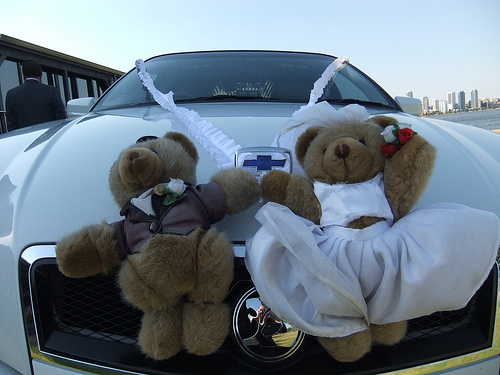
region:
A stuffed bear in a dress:
[254, 107, 499, 359]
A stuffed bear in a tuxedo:
[58, 129, 260, 359]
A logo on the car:
[234, 148, 291, 176]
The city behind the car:
[424, 90, 496, 114]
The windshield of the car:
[99, 54, 400, 108]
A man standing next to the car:
[3, 62, 67, 120]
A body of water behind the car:
[423, 107, 498, 130]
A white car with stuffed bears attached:
[2, 51, 497, 374]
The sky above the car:
[1, 0, 497, 102]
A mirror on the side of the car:
[397, 97, 421, 113]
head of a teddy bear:
[89, 112, 216, 207]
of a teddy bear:
[286, 99, 413, 198]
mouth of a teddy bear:
[119, 145, 162, 190]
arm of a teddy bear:
[55, 204, 115, 279]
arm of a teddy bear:
[220, 145, 274, 227]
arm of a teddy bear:
[254, 170, 313, 220]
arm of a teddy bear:
[393, 127, 445, 181]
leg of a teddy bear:
[128, 287, 210, 370]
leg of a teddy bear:
[171, 285, 245, 362]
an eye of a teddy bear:
[312, 127, 342, 163]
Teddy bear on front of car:
[53, 126, 255, 356]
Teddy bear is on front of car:
[52, 125, 252, 360]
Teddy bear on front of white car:
[45, 125, 255, 355]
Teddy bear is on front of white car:
[41, 122, 256, 362]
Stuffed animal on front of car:
[45, 124, 261, 362]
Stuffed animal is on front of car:
[47, 124, 262, 364]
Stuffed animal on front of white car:
[50, 125, 260, 363]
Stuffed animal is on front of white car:
[45, 127, 263, 362]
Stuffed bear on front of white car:
[53, 125, 260, 358]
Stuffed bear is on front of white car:
[52, 125, 261, 363]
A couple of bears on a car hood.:
[51, 107, 498, 366]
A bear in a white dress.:
[252, 83, 492, 348]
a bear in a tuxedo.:
[46, 125, 253, 366]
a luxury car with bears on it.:
[2, 46, 495, 372]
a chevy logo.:
[210, 135, 308, 191]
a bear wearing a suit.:
[108, 156, 240, 277]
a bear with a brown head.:
[90, 120, 195, 221]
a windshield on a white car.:
[73, 43, 398, 118]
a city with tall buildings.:
[400, 80, 480, 111]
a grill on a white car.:
[11, 231, 493, 365]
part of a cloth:
[417, 257, 424, 273]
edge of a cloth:
[293, 242, 316, 287]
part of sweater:
[323, 212, 336, 238]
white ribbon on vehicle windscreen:
[132, 38, 350, 170]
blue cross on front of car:
[237, 137, 290, 184]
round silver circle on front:
[225, 284, 307, 353]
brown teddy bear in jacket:
[47, 129, 269, 355]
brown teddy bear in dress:
[248, 100, 483, 355]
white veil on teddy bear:
[275, 95, 391, 145]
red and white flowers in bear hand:
[374, 111, 411, 169]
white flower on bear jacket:
[165, 176, 196, 203]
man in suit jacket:
[7, 63, 64, 129]